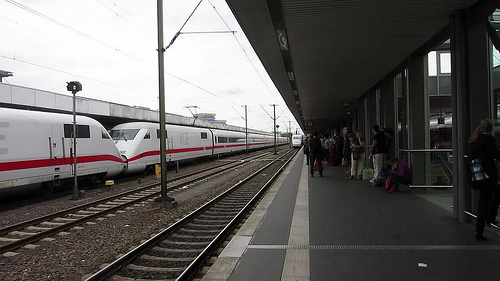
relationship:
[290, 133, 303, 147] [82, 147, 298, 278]
train on tracks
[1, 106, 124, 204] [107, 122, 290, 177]
train touching train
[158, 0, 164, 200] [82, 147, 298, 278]
pole by tracks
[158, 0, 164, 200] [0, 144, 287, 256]
pole by tracks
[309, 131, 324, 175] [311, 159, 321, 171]
person carrying a bag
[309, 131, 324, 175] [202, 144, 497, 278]
person standing on boarding platform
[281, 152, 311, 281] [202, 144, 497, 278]
stripe on boarding platform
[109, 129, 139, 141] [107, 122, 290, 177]
windshield on train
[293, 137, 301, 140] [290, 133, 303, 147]
windshield on train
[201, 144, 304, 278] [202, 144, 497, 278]
stripe on boarding platform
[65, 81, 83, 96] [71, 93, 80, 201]
train signal on post